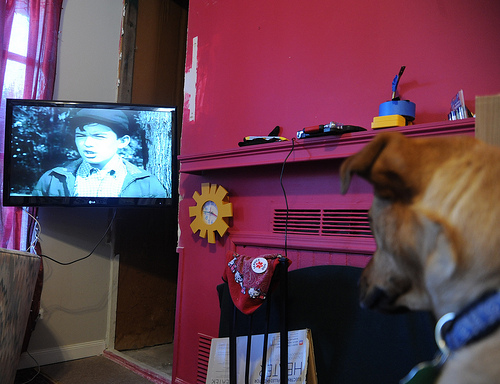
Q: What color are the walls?
A: Purple.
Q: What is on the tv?
A: Black and white movie.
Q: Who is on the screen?
A: A boy.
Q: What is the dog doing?
A: Watching tv.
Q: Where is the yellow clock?
A: On the wall.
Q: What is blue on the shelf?
A: Roll of tape.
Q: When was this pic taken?
A: During the day.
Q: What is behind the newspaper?
A: Fireplace.